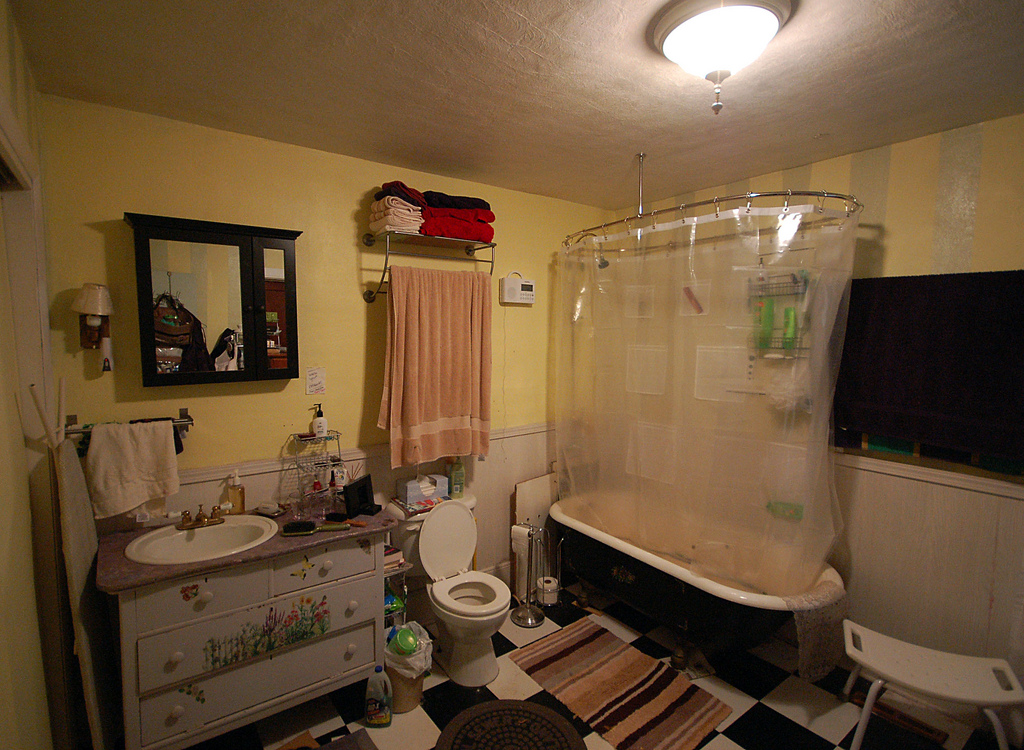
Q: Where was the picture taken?
A: In a bathroom.